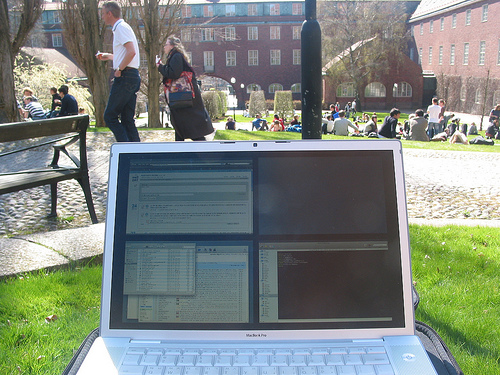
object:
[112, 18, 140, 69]
shirt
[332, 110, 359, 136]
person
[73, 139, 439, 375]
laptop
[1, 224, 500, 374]
grass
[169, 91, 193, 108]
bag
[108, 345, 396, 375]
keyboard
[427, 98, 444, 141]
man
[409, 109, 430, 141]
man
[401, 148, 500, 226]
ground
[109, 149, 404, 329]
screen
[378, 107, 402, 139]
person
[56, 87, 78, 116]
person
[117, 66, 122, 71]
watch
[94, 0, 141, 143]
man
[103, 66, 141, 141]
blue pants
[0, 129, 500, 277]
pathway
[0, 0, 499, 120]
building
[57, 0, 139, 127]
tree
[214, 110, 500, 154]
grass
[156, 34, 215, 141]
woman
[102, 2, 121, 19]
grey hair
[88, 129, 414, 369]
elephant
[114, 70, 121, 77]
hand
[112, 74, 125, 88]
pocket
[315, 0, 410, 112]
tree